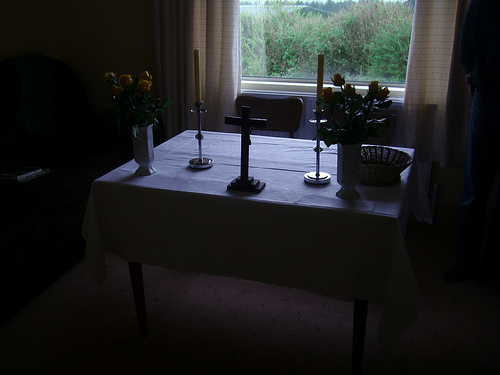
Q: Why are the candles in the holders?
A: To keep upright.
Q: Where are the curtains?
A: On the window.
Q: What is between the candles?
A: Cross.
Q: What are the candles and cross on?
A: Table.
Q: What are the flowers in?
A: Vases.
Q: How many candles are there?
A: Two.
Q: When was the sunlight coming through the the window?
A: Daytime.